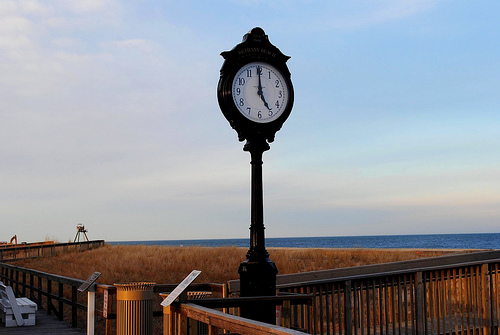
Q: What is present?
A: Clock.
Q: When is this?
A: Daytime.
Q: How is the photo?
A: Clear.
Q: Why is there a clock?
A: To tell time.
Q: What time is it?
A: 5 pm.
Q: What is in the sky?
A: Clouds.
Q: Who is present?
A: No one.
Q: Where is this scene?
A: Near the ocean.